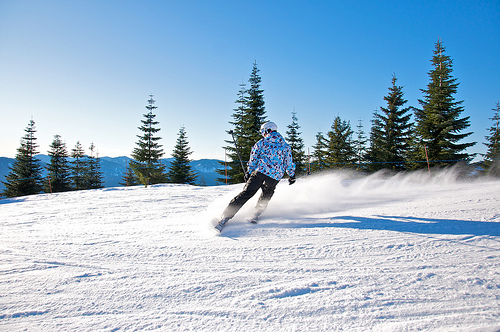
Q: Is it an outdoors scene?
A: Yes, it is outdoors.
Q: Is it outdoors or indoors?
A: It is outdoors.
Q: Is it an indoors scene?
A: No, it is outdoors.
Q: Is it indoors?
A: No, it is outdoors.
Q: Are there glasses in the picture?
A: No, there are no glasses.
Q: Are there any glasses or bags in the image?
A: No, there are no glasses or bags.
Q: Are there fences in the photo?
A: No, there are no fences.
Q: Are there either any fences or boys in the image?
A: No, there are no fences or boys.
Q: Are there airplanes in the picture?
A: No, there are no airplanes.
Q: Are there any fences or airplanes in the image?
A: No, there are no airplanes or fences.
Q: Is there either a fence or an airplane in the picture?
A: No, there are no airplanes or fences.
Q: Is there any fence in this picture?
A: No, there are no fences.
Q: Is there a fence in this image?
A: No, there are no fences.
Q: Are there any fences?
A: No, there are no fences.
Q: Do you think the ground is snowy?
A: Yes, the ground is snowy.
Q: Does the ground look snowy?
A: Yes, the ground is snowy.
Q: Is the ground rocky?
A: No, the ground is snowy.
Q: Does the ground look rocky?
A: No, the ground is snowy.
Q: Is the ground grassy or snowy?
A: The ground is snowy.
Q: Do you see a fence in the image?
A: No, there are no fences.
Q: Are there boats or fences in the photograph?
A: No, there are no fences or boats.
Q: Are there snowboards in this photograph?
A: No, there are no snowboards.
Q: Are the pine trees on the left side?
A: Yes, the pine trees are on the left of the image.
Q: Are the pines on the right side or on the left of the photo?
A: The pines are on the left of the image.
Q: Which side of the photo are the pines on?
A: The pines are on the left of the image.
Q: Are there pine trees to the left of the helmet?
A: Yes, there are pine trees to the left of the helmet.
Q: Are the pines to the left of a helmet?
A: Yes, the pines are to the left of a helmet.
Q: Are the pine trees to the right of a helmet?
A: No, the pine trees are to the left of a helmet.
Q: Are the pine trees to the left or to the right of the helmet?
A: The pine trees are to the left of the helmet.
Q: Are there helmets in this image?
A: Yes, there is a helmet.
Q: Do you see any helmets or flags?
A: Yes, there is a helmet.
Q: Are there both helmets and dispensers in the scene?
A: No, there is a helmet but no dispensers.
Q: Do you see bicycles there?
A: No, there are no bicycles.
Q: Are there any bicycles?
A: No, there are no bicycles.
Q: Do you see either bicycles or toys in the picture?
A: No, there are no bicycles or toys.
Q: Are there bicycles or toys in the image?
A: No, there are no bicycles or toys.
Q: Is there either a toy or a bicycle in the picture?
A: No, there are no bicycles or toys.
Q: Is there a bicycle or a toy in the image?
A: No, there are no bicycles or toys.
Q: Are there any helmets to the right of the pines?
A: Yes, there is a helmet to the right of the pines.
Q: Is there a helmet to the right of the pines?
A: Yes, there is a helmet to the right of the pines.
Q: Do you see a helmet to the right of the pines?
A: Yes, there is a helmet to the right of the pines.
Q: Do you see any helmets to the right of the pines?
A: Yes, there is a helmet to the right of the pines.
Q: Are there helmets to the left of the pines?
A: No, the helmet is to the right of the pines.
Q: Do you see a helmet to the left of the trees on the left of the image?
A: No, the helmet is to the right of the pines.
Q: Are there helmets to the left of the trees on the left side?
A: No, the helmet is to the right of the pines.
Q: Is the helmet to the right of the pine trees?
A: Yes, the helmet is to the right of the pine trees.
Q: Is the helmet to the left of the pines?
A: No, the helmet is to the right of the pines.